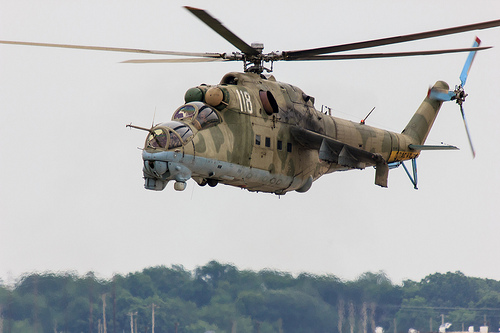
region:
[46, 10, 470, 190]
helicopter in flight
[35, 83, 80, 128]
white clouds in blue sky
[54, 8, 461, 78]
propeller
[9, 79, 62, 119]
white clouds in blue sky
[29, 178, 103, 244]
white clouds in blue sky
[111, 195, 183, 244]
white clouds in blue sky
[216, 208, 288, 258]
white clouds in blue sky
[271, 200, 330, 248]
white clouds in blue sky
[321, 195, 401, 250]
white clouds in blue sky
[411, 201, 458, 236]
white clouds in blue sky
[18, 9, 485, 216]
camo colored helicopter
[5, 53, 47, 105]
white clouds in blue sky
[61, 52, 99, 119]
white clouds in blue sky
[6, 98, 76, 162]
white clouds in blue sky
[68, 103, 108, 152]
white clouds in blue sky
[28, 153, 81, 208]
white clouds in blue sky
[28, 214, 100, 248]
white clouds in blue sky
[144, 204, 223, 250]
white clouds in blue sky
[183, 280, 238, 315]
distant trees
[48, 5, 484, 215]
helicopter in the air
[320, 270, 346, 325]
tree on the ground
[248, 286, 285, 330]
tree on the ground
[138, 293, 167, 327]
tree on the ground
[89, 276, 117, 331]
tree on the ground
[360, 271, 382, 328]
tree on the ground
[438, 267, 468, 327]
tree on the ground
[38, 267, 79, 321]
tree on the ground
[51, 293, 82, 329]
tree on the ground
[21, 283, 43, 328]
tree on the ground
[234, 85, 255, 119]
Number 118 on the helicopter.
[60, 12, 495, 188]
Army helicopter in the air.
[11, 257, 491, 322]
Trees in the background.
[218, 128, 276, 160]
Camoflauge paint on the helicopter.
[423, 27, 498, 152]
Rear propeller of a helicopter.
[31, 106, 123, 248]
Clear sky in the background.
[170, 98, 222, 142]
Cockpit of a helicopter.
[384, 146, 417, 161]
Yellow paint on the back of helicopter.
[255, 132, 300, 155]
Windows on the side of copter.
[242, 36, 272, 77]
Motor of the central propeller.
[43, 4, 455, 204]
helicopter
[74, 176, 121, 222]
white clouds in blue sky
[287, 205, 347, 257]
white clouds in blue sky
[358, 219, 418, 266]
white clouds in blue sky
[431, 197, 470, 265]
white clouds in blue sky